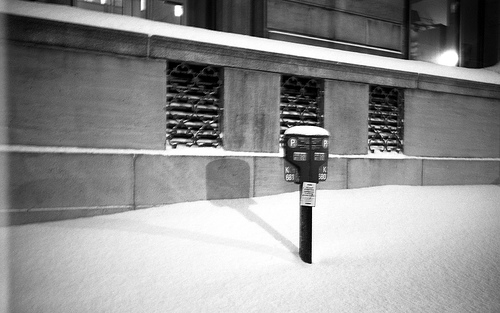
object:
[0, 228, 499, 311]
street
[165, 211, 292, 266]
of snow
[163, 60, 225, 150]
window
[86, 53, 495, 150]
basement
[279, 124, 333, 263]
parking meter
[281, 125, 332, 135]
snow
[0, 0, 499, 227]
building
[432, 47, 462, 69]
light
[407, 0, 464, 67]
window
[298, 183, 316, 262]
pole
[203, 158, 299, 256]
shadow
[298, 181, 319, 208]
meter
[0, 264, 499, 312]
on ground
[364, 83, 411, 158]
vents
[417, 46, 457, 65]
reflection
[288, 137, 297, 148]
p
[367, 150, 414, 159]
snow on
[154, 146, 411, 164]
under vents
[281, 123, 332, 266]
sign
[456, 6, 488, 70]
bars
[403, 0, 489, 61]
windows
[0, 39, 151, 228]
wall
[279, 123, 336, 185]
sign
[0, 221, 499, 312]
ground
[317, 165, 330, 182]
sign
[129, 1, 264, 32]
decorations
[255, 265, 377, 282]
snow covering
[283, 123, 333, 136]
top of meter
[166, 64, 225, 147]
bars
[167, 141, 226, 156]
snow